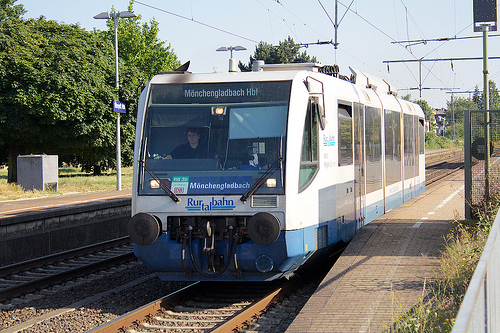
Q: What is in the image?
A: A train.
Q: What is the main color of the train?
A: White.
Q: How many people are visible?
A: One.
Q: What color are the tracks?
A: Brown.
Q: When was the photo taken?
A: A sunny day.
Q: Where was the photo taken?
A: Beside the train tracks.